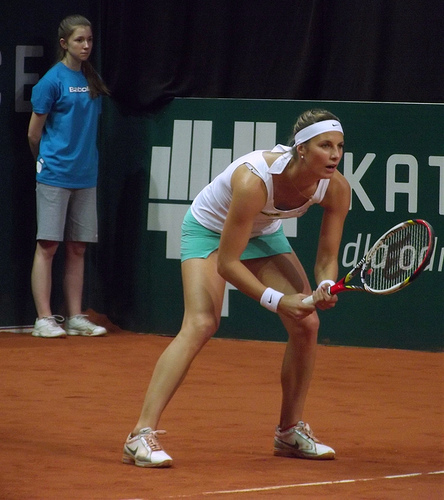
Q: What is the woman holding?
A: Tennis racket.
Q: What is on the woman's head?
A: Band.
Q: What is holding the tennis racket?
A: Hands.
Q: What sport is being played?
A: Tennis.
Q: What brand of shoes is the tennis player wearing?
A: Nike.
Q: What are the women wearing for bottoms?
A: Shorts.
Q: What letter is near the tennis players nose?
A: K.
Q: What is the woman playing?
A: Tennis.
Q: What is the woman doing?
A: Bending over.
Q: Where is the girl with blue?
A: On the side.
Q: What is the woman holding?
A: A racket.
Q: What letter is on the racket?
A: W.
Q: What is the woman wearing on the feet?
A: Tennis shoes.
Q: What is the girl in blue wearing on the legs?
A: Gray shorts.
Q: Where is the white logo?
A: On the wall.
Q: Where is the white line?
A: On the clay court.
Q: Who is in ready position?
A: The tennis player.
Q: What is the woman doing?
A: Holding the tennis racket.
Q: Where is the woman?
A: On the tennis court.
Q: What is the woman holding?
A: A tennis racket.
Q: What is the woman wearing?
A: A white tank top.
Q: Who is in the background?
A: A young girl.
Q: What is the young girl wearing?
A: A blue shirt.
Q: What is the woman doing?
A: Playing tennis.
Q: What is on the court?
A: A white line.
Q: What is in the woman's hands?
A: A tennis racket.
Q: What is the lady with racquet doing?
A: Bending forward.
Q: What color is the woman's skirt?
A: Green.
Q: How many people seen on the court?
A: Two.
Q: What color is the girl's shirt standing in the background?
A: Blue.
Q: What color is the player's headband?
A: White.